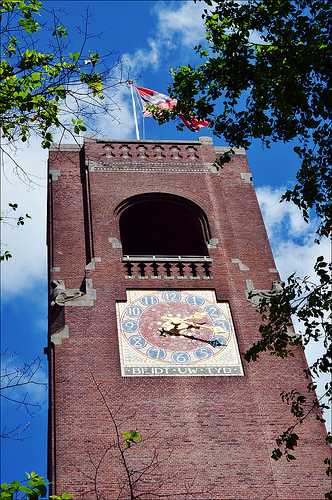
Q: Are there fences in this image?
A: No, there are no fences.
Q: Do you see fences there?
A: No, there are no fences.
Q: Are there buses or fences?
A: No, there are no fences or buses.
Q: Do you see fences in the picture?
A: No, there are no fences.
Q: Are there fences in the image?
A: No, there are no fences.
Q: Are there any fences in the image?
A: No, there are no fences.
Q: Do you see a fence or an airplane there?
A: No, there are no fences or airplanes.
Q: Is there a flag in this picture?
A: Yes, there is a flag.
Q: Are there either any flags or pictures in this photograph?
A: Yes, there is a flag.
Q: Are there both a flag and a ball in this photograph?
A: No, there is a flag but no balls.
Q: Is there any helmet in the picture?
A: No, there are no helmets.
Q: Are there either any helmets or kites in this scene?
A: No, there are no helmets or kites.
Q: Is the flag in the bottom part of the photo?
A: No, the flag is in the top of the image.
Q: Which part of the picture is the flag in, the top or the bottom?
A: The flag is in the top of the image.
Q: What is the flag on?
A: The flag is on the building.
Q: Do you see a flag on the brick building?
A: Yes, there is a flag on the building.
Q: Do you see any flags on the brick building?
A: Yes, there is a flag on the building.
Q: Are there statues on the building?
A: No, there is a flag on the building.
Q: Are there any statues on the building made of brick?
A: No, there is a flag on the building.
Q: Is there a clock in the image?
A: Yes, there is a clock.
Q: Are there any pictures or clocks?
A: Yes, there is a clock.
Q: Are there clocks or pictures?
A: Yes, there is a clock.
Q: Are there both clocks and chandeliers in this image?
A: No, there is a clock but no chandeliers.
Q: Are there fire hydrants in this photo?
A: No, there are no fire hydrants.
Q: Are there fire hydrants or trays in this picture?
A: No, there are no fire hydrants or trays.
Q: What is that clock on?
A: The clock is on the building.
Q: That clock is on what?
A: The clock is on the building.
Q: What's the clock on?
A: The clock is on the building.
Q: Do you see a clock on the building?
A: Yes, there is a clock on the building.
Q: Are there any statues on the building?
A: No, there is a clock on the building.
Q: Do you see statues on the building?
A: No, there is a clock on the building.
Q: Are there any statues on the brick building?
A: No, there is a clock on the building.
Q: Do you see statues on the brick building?
A: No, there is a clock on the building.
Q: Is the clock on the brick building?
A: Yes, the clock is on the building.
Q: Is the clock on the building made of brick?
A: Yes, the clock is on the building.